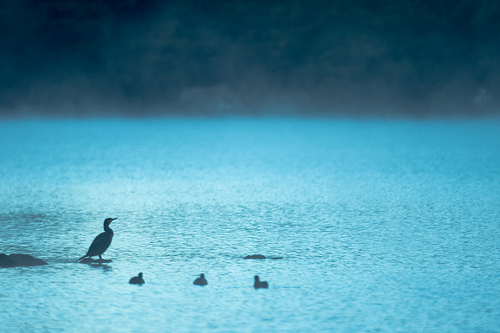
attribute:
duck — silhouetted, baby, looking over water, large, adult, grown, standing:
[70, 205, 129, 291]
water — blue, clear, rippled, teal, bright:
[226, 175, 422, 243]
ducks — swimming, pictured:
[78, 211, 307, 313]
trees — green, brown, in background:
[251, 26, 441, 90]